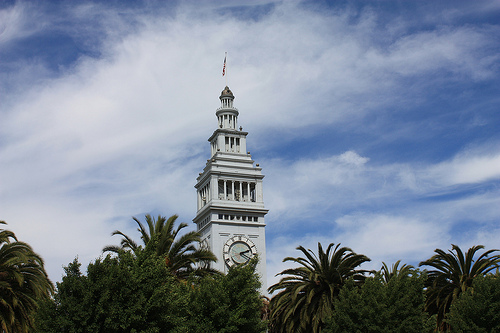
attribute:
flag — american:
[220, 51, 228, 77]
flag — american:
[215, 53, 230, 73]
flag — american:
[217, 52, 235, 73]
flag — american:
[217, 52, 234, 78]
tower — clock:
[193, 83, 267, 328]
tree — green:
[3, 218, 63, 331]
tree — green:
[183, 252, 265, 332]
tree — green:
[101, 212, 221, 298]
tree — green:
[260, 234, 380, 330]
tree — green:
[411, 239, 498, 325]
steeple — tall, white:
[184, 80, 292, 309]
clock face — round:
[211, 224, 263, 278]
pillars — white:
[211, 176, 277, 219]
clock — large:
[198, 209, 278, 296]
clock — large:
[194, 213, 270, 287]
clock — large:
[211, 212, 285, 308]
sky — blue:
[317, 115, 447, 241]